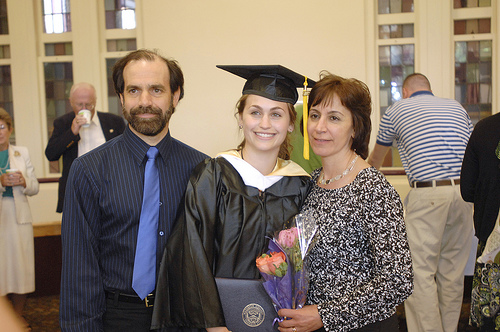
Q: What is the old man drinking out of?
A: Cup.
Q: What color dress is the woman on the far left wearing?
A: White.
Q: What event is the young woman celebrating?
A: School graduation.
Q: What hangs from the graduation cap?
A: Yellow tassel.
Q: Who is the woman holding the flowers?
A: Mother.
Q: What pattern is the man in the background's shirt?
A: Blue and white stripes.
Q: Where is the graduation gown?
A: Girl in forefront.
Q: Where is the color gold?
A: Girl's shoulders.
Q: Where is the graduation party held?
A: Building on campus.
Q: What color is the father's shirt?
A: Pinstripe blue.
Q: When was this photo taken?
A: During a graduation ceremony.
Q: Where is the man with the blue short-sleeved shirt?
A: In the background with his back toward the camera.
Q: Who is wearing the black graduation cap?
A: The young woman.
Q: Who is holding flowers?
A: The woman in the black and white shirt.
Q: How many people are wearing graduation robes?
A: One.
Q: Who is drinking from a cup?
A: The man with the white shirt and black jacket.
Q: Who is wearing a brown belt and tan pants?
A: The man in the striped shirt.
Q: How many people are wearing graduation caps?
A: One.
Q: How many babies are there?
A: None.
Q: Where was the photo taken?
A: Inside a venue.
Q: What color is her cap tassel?
A: Yellow.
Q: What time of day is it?
A: Daytime.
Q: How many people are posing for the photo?
A: Three.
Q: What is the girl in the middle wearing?
A: Graduation cap and gown.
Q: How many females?
A: Two.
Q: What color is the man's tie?
A: Light blue.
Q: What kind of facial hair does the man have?
A: Beard and moustache.